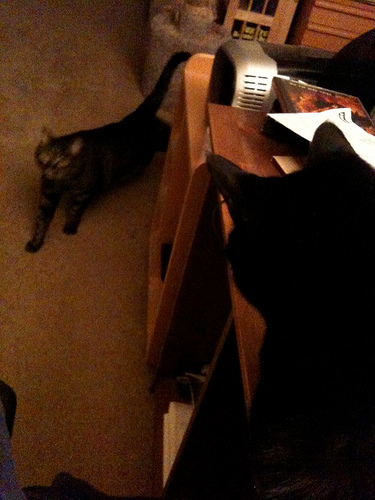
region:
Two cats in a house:
[6, 6, 373, 492]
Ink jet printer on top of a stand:
[197, 30, 373, 142]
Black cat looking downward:
[204, 119, 365, 497]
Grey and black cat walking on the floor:
[20, 88, 159, 262]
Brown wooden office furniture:
[151, 31, 372, 489]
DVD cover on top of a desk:
[276, 64, 372, 155]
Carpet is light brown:
[11, 4, 160, 456]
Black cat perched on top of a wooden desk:
[166, 109, 369, 495]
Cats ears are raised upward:
[199, 86, 353, 285]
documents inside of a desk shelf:
[158, 299, 344, 474]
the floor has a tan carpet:
[1, 3, 164, 498]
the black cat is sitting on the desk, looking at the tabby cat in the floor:
[197, 119, 372, 497]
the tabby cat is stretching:
[21, 47, 194, 253]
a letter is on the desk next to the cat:
[271, 102, 374, 182]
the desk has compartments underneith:
[143, 100, 372, 498]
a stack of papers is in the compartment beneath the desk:
[159, 398, 198, 493]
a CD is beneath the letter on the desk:
[272, 74, 373, 144]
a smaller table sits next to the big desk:
[139, 47, 240, 366]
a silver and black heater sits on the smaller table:
[203, 36, 299, 135]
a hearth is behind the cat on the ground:
[129, 0, 252, 116]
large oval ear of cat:
[194, 145, 268, 209]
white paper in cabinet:
[160, 401, 193, 474]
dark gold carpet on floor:
[48, 328, 132, 432]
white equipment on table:
[223, 49, 279, 124]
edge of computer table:
[196, 100, 236, 135]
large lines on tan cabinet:
[304, 11, 340, 41]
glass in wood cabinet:
[250, 1, 286, 18]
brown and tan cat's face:
[24, 143, 89, 196]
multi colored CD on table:
[264, 71, 363, 126]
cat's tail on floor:
[153, 47, 187, 131]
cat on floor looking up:
[0, 50, 195, 257]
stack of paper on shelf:
[151, 378, 205, 486]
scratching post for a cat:
[125, 13, 236, 117]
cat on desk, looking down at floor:
[196, 114, 373, 410]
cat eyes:
[34, 145, 78, 173]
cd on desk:
[267, 68, 374, 137]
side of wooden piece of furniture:
[211, 1, 304, 49]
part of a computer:
[188, 33, 349, 126]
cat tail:
[136, 49, 195, 121]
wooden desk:
[174, 100, 317, 498]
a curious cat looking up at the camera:
[12, 50, 186, 245]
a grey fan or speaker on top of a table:
[199, 39, 277, 121]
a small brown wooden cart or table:
[128, 54, 220, 367]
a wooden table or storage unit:
[123, 88, 365, 498]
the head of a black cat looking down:
[186, 107, 374, 348]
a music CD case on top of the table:
[266, 73, 374, 137]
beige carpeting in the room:
[9, 11, 129, 109]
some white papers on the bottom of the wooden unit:
[160, 403, 195, 487]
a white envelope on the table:
[269, 97, 374, 157]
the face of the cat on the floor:
[39, 150, 70, 176]